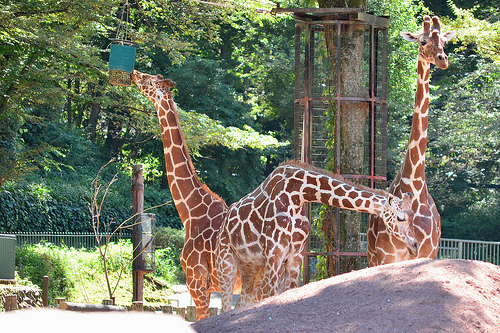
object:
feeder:
[107, 36, 138, 87]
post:
[131, 164, 157, 305]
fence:
[0, 231, 499, 331]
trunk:
[321, 0, 372, 278]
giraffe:
[213, 159, 420, 314]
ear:
[387, 195, 397, 210]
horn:
[400, 192, 412, 210]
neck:
[295, 165, 388, 217]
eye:
[394, 215, 406, 224]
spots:
[281, 177, 309, 196]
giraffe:
[129, 69, 231, 322]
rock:
[188, 257, 500, 331]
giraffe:
[366, 14, 448, 269]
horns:
[422, 13, 432, 36]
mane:
[278, 159, 390, 197]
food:
[107, 69, 134, 86]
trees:
[1, 0, 500, 242]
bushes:
[14, 227, 182, 306]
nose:
[410, 241, 418, 250]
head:
[131, 69, 178, 102]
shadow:
[188, 258, 477, 333]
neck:
[152, 100, 221, 206]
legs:
[181, 264, 214, 323]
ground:
[0, 257, 500, 332]